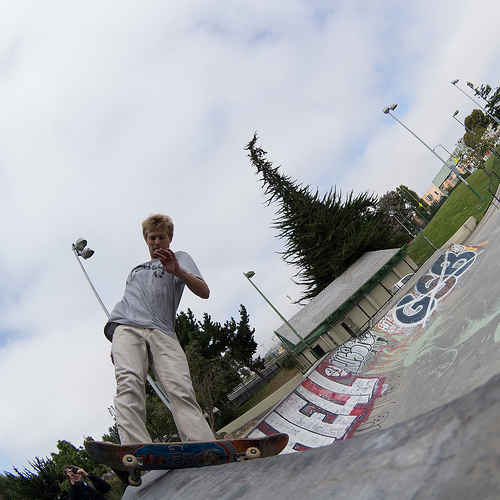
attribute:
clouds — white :
[8, 16, 65, 68]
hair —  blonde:
[142, 215, 173, 234]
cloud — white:
[40, 29, 222, 143]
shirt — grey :
[104, 248, 204, 338]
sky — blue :
[164, 39, 434, 131]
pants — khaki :
[107, 322, 224, 452]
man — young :
[75, 203, 247, 473]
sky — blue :
[5, 10, 373, 194]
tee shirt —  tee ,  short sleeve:
[104, 250, 204, 332]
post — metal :
[68, 235, 183, 417]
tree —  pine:
[200, 104, 463, 298]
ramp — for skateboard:
[139, 239, 498, 499]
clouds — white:
[3, 10, 489, 428]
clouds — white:
[3, 5, 474, 383]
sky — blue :
[2, 3, 497, 483]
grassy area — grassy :
[398, 144, 498, 267]